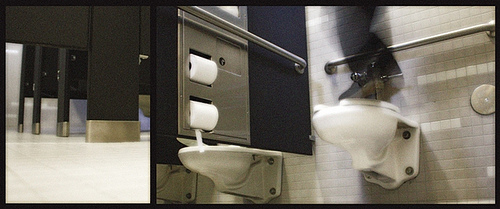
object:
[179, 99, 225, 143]
paper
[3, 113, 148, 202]
floor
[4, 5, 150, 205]
mirror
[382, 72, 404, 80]
lever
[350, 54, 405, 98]
pipes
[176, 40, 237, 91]
basket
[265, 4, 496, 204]
tiles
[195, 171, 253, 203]
tiles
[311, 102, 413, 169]
bowl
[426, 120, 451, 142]
ground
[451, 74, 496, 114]
lid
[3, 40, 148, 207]
tile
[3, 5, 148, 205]
room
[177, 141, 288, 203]
toilet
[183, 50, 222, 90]
paper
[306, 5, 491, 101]
back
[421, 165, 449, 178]
ground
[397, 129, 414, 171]
panel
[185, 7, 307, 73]
handle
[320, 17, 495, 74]
bar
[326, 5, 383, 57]
shadow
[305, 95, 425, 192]
toilet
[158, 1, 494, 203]
photo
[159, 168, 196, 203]
toilet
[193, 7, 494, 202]
wall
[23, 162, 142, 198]
tile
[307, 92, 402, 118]
lid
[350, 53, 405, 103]
metal